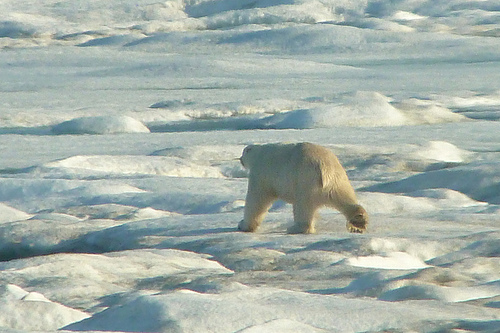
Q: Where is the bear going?
A: Away.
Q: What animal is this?
A: Bear.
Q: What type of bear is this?
A: Polar Bear.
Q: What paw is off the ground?
A: Back right.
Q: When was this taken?
A: In the daytime.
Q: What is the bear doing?
A: Walking.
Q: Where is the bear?
A: In the snow.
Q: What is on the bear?
A: Snow.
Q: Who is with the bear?
A: No people.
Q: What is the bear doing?
A: Walking.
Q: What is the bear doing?
A: Walking.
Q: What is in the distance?
A: Snow.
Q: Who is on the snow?
A: A polar bear.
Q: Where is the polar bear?
A: Walking on the snow.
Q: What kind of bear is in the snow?
A: A white polar bear.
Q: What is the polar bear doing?
A: Walking across the ice.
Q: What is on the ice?
A: There are small hills of snow on the ice.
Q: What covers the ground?
A: Snow.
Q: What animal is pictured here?
A: Polar bear.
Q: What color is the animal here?
A: White.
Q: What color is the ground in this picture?
A: White.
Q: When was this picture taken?
A: Daytime.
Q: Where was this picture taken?
A: The Arctic.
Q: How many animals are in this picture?
A: One.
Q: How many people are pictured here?
A: Zero.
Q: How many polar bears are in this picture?
A: One.